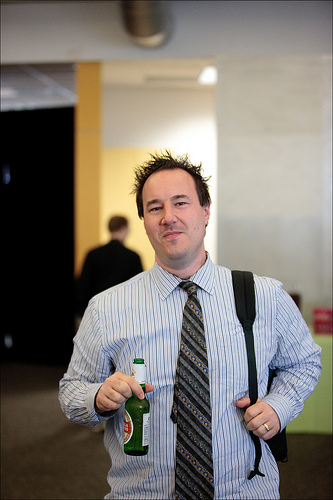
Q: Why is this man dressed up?
A: Came from work.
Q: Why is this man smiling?
A: Work is over.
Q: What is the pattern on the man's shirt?
A: Pinstripe.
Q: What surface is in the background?
A: A table.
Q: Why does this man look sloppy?
A: Untucked shirt.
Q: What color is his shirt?
A: Blue.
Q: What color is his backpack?
A: Black.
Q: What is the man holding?
A: Beer.